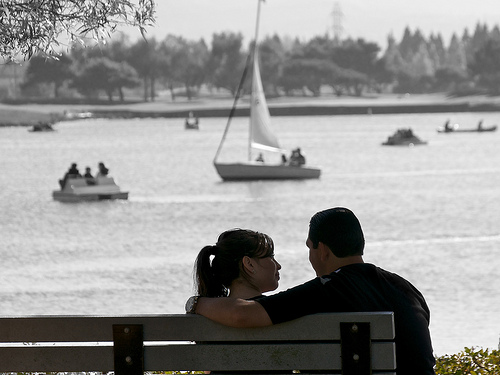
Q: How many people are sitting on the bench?
A: 2.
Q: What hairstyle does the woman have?
A: Ponytail.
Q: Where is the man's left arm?
A: Around the woman's shoulders.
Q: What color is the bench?
A: Gray.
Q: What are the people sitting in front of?
A: A lake.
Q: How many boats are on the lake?
A: Six.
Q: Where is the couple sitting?
A: On a bench.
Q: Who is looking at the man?
A: The woman.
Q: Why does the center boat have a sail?
A: To catch the wind.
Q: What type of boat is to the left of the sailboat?
A: Pedal boat.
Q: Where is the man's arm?
A: Around the woman.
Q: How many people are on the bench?
A: Two.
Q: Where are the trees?
A: Across the lake.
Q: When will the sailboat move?
A: When the wind blows.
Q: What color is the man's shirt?
A: Black.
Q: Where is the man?
A: On the right.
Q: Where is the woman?
A: On the left.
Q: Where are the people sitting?
A: A bench.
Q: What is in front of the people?
A: Water.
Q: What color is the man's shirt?
A: Black.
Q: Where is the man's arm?
A: Around the woman.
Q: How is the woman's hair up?
A: A ponytail.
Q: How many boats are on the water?
A: Six.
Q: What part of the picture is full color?
A: The people on the bench.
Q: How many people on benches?
A: 2.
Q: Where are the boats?
A: In water.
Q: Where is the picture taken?
A: At the lake.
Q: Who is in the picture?
A: A couple.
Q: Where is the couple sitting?
A: On a bench.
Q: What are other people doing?
A: Boating.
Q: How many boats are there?
A: Six.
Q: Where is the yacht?
A: In the middle of the lake.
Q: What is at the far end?
A: A canoe.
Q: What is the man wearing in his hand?
A: A watch.